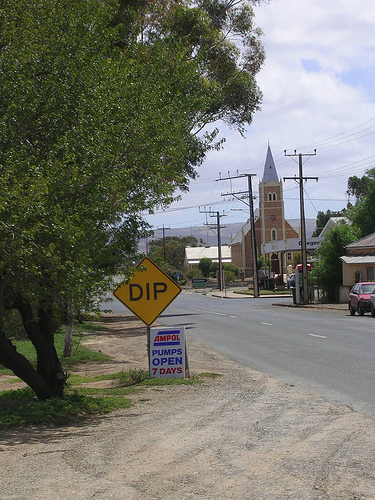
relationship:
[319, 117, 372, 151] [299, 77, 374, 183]
cables in air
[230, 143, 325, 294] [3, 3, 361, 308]
church in background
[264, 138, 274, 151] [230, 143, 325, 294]
cross on church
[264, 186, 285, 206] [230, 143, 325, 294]
windows on church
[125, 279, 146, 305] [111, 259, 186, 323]
letter on sign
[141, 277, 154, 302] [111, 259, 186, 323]
letter on sign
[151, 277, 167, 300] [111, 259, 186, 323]
letter on sign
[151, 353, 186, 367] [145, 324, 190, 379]
word on sign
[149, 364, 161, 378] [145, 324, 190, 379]
number on sign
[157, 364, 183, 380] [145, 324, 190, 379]
word on sign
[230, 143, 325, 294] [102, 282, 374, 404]
church on street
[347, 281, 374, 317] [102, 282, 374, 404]
car on street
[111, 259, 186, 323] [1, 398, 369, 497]
sign on road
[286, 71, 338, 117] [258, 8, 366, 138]
clouds in sky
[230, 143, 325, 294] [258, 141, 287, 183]
church has steeple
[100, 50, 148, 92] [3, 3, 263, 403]
leaves on tree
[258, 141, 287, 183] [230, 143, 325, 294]
steeple on church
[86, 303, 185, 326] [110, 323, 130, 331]
shadow on gravel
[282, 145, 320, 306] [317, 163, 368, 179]
pole has wires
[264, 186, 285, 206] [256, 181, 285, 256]
windows on tower